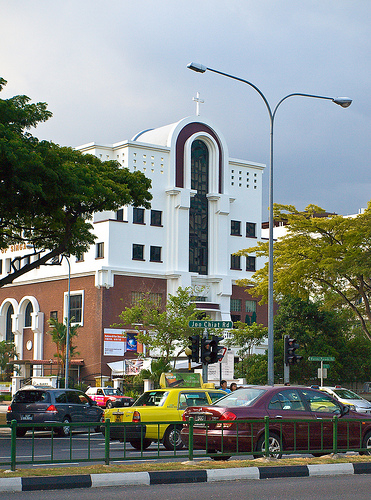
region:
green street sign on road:
[187, 317, 236, 331]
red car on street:
[193, 385, 368, 445]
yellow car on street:
[105, 387, 182, 441]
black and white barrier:
[80, 472, 249, 481]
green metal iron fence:
[82, 419, 167, 462]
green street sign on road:
[298, 351, 332, 363]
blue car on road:
[0, 385, 88, 429]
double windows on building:
[129, 237, 163, 263]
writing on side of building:
[1, 236, 20, 254]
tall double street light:
[183, 57, 339, 273]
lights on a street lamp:
[184, 58, 358, 115]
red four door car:
[176, 386, 369, 442]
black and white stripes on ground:
[43, 463, 346, 484]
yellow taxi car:
[92, 374, 231, 447]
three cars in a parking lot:
[6, 385, 357, 463]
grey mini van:
[0, 384, 118, 438]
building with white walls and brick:
[18, 267, 118, 381]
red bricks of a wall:
[73, 324, 101, 360]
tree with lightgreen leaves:
[286, 207, 368, 301]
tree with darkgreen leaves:
[1, 168, 135, 214]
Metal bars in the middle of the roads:
[1, 414, 370, 468]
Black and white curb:
[2, 461, 369, 491]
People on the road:
[218, 380, 291, 390]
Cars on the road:
[5, 384, 369, 458]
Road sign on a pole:
[307, 355, 334, 361]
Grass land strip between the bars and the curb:
[1, 452, 369, 476]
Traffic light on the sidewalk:
[184, 332, 304, 371]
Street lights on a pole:
[185, 59, 354, 389]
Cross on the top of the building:
[191, 90, 205, 115]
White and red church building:
[0, 90, 304, 385]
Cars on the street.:
[7, 379, 367, 457]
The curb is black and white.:
[1, 455, 358, 489]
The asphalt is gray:
[1, 463, 367, 499]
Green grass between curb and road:
[4, 451, 369, 470]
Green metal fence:
[2, 396, 368, 474]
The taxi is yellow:
[111, 372, 264, 452]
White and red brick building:
[13, 112, 288, 399]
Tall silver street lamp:
[187, 49, 369, 389]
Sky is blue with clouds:
[0, 13, 361, 218]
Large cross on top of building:
[187, 89, 210, 125]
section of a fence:
[173, 435, 193, 444]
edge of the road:
[208, 480, 240, 484]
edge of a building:
[98, 306, 111, 330]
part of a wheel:
[261, 437, 277, 450]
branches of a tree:
[294, 333, 330, 347]